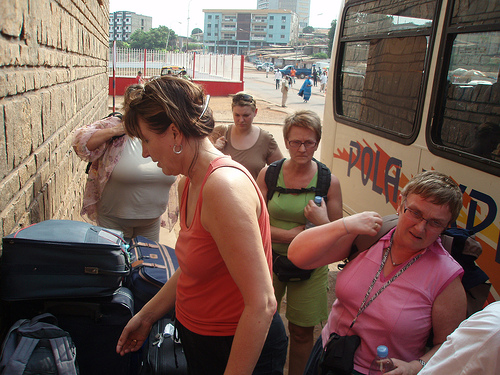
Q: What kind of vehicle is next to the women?
A: A bus.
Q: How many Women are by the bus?
A: 5.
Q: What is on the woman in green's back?
A: A backpack.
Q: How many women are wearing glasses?
A: 2.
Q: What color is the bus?
A: White.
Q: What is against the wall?
A: Luggage.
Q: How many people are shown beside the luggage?
A: Six.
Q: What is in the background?
A: Buildings.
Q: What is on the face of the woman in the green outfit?
A: Glasses.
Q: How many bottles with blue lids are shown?
A: Two.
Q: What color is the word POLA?
A: Black.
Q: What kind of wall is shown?
A: Rock.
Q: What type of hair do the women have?
A: Short hair.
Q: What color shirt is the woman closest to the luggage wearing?
A: Orange.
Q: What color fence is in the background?
A: Red.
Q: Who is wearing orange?
A: One woman.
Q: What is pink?
A: Woman's shirt.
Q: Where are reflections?
A: On windows.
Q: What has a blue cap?
A: Water bottle.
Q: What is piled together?
A: Bags.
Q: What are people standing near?
A: A bus.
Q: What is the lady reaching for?
A: Luggage.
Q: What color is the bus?
A: White.